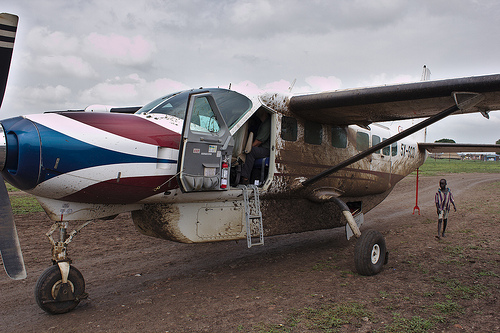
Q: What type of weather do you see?
A: It is cloudy.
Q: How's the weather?
A: It is cloudy.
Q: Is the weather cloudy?
A: Yes, it is cloudy.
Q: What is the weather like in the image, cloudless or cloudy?
A: It is cloudy.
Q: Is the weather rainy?
A: No, it is cloudy.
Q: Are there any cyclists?
A: No, there are no cyclists.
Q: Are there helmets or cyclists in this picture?
A: No, there are no cyclists or helmets.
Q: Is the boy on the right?
A: Yes, the boy is on the right of the image.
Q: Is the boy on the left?
A: No, the boy is on the right of the image.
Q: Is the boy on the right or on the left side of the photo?
A: The boy is on the right of the image.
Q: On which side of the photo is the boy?
A: The boy is on the right of the image.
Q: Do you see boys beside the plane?
A: Yes, there is a boy beside the plane.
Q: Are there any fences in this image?
A: No, there are no fences.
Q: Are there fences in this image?
A: No, there are no fences.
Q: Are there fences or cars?
A: No, there are no fences or cars.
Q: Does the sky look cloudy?
A: Yes, the sky is cloudy.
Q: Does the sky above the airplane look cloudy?
A: Yes, the sky is cloudy.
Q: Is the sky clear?
A: No, the sky is cloudy.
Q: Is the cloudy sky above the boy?
A: Yes, the sky is above the boy.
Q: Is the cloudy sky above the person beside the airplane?
A: Yes, the sky is above the boy.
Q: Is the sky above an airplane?
A: Yes, the sky is above an airplane.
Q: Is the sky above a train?
A: No, the sky is above an airplane.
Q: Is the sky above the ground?
A: Yes, the sky is above the ground.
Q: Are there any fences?
A: No, there are no fences.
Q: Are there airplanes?
A: Yes, there is an airplane.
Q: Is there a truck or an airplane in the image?
A: Yes, there is an airplane.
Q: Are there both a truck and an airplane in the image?
A: No, there is an airplane but no trucks.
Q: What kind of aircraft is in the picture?
A: The aircraft is an airplane.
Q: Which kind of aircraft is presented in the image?
A: The aircraft is an airplane.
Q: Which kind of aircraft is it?
A: The aircraft is an airplane.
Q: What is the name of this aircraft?
A: That is an airplane.